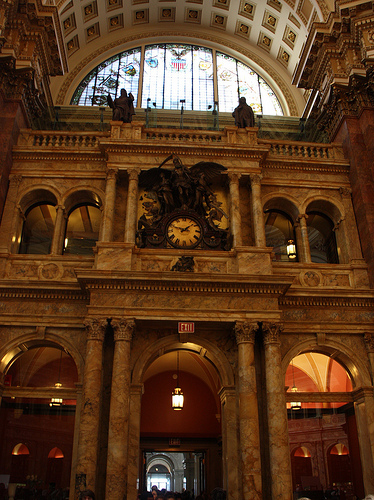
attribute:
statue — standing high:
[106, 87, 138, 125]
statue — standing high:
[232, 97, 257, 129]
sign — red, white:
[177, 319, 196, 334]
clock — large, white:
[165, 215, 204, 251]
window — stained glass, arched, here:
[53, 22, 308, 122]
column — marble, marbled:
[235, 324, 260, 500]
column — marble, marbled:
[106, 318, 134, 500]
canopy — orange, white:
[282, 350, 355, 410]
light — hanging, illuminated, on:
[169, 346, 189, 414]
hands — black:
[171, 222, 194, 235]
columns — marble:
[71, 319, 296, 500]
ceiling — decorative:
[41, 3, 327, 87]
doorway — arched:
[144, 453, 177, 496]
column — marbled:
[68, 314, 110, 497]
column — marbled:
[261, 320, 297, 497]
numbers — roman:
[167, 216, 200, 249]